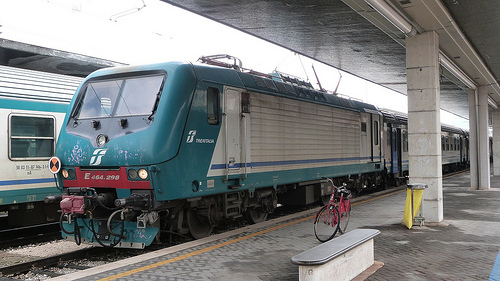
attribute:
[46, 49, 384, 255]
car — first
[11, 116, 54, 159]
window — for passenger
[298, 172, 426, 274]
bike — parked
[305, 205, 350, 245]
wheel — turned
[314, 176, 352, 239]
bicycle — pink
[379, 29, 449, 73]
lighting — flouroscent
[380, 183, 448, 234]
bag — yellow, plastic, hanging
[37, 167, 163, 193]
lights — glowing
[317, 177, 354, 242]
bicycle — red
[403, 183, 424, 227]
trash bag — yellow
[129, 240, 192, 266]
line — yellow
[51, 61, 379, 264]
train — green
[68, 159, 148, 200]
sign — train , red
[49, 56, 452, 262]
train — white, side 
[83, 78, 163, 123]
window — closed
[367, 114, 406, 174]
door — closed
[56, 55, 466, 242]
train —  aqua and white , tracks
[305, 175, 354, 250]
bike — red 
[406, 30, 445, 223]
pillar — concrete 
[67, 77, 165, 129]
windsheild — train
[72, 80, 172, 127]
train — side, window 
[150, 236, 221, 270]
line — yellow 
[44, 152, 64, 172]
headlight — round 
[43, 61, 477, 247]
train — side 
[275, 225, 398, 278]
bench — platform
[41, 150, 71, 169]
sign — black , orange 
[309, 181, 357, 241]
bike — red and black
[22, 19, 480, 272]
train — station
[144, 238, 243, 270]
line — painted , yellow 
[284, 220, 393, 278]
bench — small concrete 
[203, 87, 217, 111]
train — window , side 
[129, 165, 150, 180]
light — on the front of the train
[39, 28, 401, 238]
train — red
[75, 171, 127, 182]
paint — on the front of the train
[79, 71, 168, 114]
windows — on the front of the train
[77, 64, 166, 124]
window — on the window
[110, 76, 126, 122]
bar — metal 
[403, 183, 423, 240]
receptacle — yellow, trash, on the platform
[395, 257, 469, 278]
cement — solid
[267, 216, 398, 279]
bench — gray, light tan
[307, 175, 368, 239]
bicycle — red, parked on the platform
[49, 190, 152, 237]
train engine — blue, gray, with red trim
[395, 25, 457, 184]
column — light gray, cement, block, support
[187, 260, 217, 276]
cobblestone — on the platform, gray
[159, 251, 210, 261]
line — on the platform, yellow, painted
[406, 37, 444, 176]
columns — side by side, gray, support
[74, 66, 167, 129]
windows — of the train engine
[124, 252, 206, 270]
line — yellow, next to the train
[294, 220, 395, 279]
bench — on the platform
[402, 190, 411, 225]
bag — next to pole, trash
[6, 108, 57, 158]
window —  on the train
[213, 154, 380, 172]
line — blue, along the train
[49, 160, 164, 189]
head lights — on the train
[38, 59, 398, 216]
train — with red front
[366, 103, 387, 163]
door — on the train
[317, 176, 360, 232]
bike — red